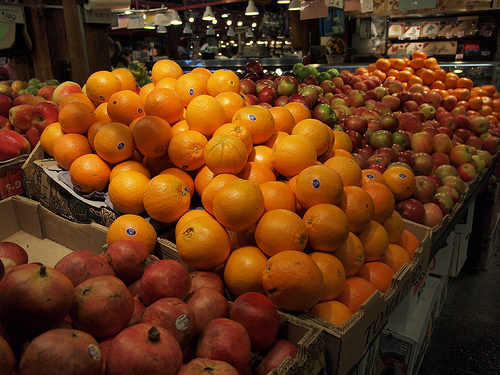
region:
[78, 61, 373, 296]
A pile of oranges.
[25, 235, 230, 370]
Pomegranates.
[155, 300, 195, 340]
A sticker is on the pomegranate.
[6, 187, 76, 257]
A cardboard box.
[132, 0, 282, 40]
Light fixtures hanging from the ceiling.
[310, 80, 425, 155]
A pile of apples.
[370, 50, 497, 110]
A pile of tangerines.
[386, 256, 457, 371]
White boxes.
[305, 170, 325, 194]
A blue sticker is on the orange.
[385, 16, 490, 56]
Boxed items on the shelf.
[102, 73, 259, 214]
pile of navel oranges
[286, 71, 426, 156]
red and green apples in a bin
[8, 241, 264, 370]
stack of pomegranets in a box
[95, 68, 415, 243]
apples and oranges on display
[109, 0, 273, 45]
row of hanging lights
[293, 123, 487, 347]
fruit in cardboard bins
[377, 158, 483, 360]
white boxes under shelf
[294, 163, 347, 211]
orange with a blue sticker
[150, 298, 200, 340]
pomegranete with a white sticker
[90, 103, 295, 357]
oranges and pomegranets on display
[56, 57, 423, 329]
oranges are on display for sale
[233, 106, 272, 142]
the oranges have blue stickers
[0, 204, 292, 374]
pomegranates are next to the oranges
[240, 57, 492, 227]
apples are next to the oranges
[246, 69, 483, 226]
the apples are green and red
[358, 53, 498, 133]
tangerines are on the end boxes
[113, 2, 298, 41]
light fixtures are hanging from the ceiling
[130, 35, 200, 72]
workers are in the background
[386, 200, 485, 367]
more boxes are on the floor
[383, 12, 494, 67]
boxes of seafood are in the background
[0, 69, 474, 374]
Boxes of fruit.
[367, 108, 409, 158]
Some apples waiting to ripen.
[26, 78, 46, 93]
SOme granny smith apples.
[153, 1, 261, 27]
Lights hang from the ceiling.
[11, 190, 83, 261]
An carboard box.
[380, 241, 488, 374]
boxes under the table.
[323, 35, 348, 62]
A basket on the counter.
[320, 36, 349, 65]
A basket of flowers.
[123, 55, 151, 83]
A bundle of bananas.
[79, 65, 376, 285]
several oranges in a pile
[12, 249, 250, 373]
multiple red pomegranates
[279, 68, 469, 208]
red and green apples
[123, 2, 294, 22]
hanging white lights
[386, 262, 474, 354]
cardboard boxes under the fruit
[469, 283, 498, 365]
dark floor beneath the fruit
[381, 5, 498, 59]
shelves filled with goods for sale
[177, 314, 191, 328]
a sticker on a pomegranate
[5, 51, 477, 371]
an indoor display of fruit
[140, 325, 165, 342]
the stem of a pomegranate